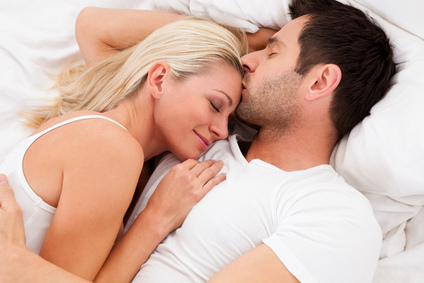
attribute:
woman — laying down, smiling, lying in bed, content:
[1, 16, 247, 282]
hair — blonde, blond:
[16, 13, 246, 133]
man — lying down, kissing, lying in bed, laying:
[1, 1, 400, 283]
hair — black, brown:
[284, 0, 400, 149]